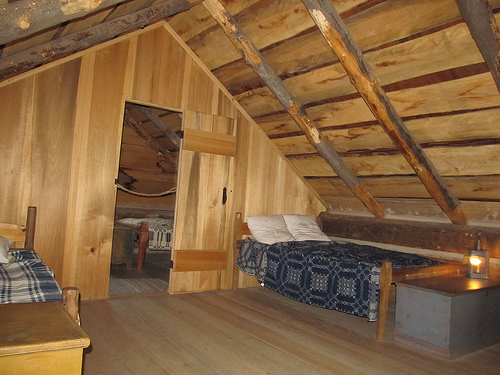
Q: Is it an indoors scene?
A: Yes, it is indoors.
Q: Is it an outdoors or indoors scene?
A: It is indoors.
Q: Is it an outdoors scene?
A: No, it is indoors.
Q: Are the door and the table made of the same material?
A: Yes, both the door and the table are made of wood.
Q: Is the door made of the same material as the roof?
A: Yes, both the door and the roof are made of wood.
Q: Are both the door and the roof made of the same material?
A: Yes, both the door and the roof are made of wood.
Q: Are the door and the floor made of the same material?
A: Yes, both the door and the floor are made of wood.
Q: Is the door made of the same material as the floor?
A: Yes, both the door and the floor are made of wood.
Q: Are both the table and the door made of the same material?
A: Yes, both the table and the door are made of wood.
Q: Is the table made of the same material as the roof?
A: Yes, both the table and the roof are made of wood.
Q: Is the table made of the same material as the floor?
A: Yes, both the table and the floor are made of wood.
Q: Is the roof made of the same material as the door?
A: Yes, both the roof and the door are made of wood.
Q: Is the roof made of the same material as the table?
A: Yes, both the roof and the table are made of wood.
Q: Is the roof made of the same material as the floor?
A: Yes, both the roof and the floor are made of wood.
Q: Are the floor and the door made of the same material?
A: Yes, both the floor and the door are made of wood.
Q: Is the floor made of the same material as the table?
A: Yes, both the floor and the table are made of wood.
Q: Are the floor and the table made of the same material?
A: Yes, both the floor and the table are made of wood.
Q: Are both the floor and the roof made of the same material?
A: Yes, both the floor and the roof are made of wood.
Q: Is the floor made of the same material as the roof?
A: Yes, both the floor and the roof are made of wood.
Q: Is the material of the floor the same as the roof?
A: Yes, both the floor and the roof are made of wood.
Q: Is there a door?
A: Yes, there is a door.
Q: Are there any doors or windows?
A: Yes, there is a door.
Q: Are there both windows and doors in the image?
A: No, there is a door but no windows.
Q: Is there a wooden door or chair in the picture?
A: Yes, there is a wood door.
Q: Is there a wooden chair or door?
A: Yes, there is a wood door.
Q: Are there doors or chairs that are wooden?
A: Yes, the door is wooden.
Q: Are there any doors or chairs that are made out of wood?
A: Yes, the door is made of wood.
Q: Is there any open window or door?
A: Yes, there is an open door.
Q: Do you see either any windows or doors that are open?
A: Yes, the door is open.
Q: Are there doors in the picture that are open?
A: Yes, there is an open door.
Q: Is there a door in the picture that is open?
A: Yes, there is a door that is open.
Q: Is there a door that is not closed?
A: Yes, there is a open door.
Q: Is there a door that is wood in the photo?
A: Yes, there is a wood door.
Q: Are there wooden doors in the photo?
A: Yes, there is a wood door.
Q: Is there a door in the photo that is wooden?
A: Yes, there is a door that is wooden.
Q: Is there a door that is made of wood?
A: Yes, there is a door that is made of wood.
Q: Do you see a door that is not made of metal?
A: Yes, there is a door that is made of wood.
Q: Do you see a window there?
A: No, there are no windows.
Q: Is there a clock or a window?
A: No, there are no windows or clocks.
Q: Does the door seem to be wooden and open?
A: Yes, the door is wooden and open.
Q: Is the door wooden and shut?
A: No, the door is wooden but open.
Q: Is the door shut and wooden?
A: No, the door is wooden but open.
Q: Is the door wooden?
A: Yes, the door is wooden.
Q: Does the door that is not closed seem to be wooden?
A: Yes, the door is wooden.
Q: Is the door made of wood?
A: Yes, the door is made of wood.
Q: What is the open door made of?
A: The door is made of wood.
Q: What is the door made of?
A: The door is made of wood.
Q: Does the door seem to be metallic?
A: No, the door is wooden.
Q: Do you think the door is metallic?
A: No, the door is wooden.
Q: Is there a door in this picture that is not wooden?
A: No, there is a door but it is wooden.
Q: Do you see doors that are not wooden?
A: No, there is a door but it is wooden.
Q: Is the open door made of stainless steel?
A: No, the door is made of wood.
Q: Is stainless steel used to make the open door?
A: No, the door is made of wood.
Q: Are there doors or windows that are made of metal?
A: No, there is a door but it is made of wood.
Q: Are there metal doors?
A: No, there is a door but it is made of wood.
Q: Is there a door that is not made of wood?
A: No, there is a door but it is made of wood.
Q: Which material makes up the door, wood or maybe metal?
A: The door is made of wood.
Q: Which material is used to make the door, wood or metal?
A: The door is made of wood.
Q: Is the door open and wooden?
A: Yes, the door is open and wooden.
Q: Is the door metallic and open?
A: No, the door is open but wooden.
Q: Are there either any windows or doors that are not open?
A: No, there is a door but it is open.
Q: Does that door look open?
A: Yes, the door is open.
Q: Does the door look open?
A: Yes, the door is open.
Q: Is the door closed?
A: No, the door is open.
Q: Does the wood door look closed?
A: No, the door is open.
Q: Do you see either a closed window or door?
A: No, there is a door but it is open.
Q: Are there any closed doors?
A: No, there is a door but it is open.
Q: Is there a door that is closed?
A: No, there is a door but it is open.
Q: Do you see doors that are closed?
A: No, there is a door but it is open.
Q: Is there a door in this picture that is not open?
A: No, there is a door but it is open.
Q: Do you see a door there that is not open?
A: No, there is a door but it is open.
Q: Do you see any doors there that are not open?
A: No, there is a door but it is open.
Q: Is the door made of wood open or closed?
A: The door is open.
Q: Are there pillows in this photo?
A: Yes, there is a pillow.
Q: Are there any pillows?
A: Yes, there is a pillow.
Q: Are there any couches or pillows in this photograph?
A: Yes, there is a pillow.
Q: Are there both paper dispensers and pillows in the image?
A: No, there is a pillow but no paper dispensers.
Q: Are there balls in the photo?
A: No, there are no balls.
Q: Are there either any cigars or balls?
A: No, there are no balls or cigars.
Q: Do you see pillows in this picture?
A: Yes, there is a pillow.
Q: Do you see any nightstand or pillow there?
A: Yes, there is a pillow.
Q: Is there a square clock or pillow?
A: Yes, there is a square pillow.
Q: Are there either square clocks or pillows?
A: Yes, there is a square pillow.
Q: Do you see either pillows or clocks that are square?
A: Yes, the pillow is square.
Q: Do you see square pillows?
A: Yes, there is a square pillow.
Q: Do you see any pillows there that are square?
A: Yes, there is a pillow that is square.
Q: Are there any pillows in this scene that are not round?
A: Yes, there is a square pillow.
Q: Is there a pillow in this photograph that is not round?
A: Yes, there is a square pillow.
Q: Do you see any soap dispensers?
A: No, there are no soap dispensers.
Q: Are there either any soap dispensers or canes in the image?
A: No, there are no soap dispensers or canes.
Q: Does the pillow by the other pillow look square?
A: Yes, the pillow is square.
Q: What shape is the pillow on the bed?
A: The pillow is square.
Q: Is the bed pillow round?
A: No, the pillow is square.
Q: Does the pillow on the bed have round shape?
A: No, the pillow is square.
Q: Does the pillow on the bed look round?
A: No, the pillow is square.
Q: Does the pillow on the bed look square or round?
A: The pillow is square.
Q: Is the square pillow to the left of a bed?
A: No, the pillow is to the right of a bed.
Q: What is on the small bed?
A: The pillow is on the bed.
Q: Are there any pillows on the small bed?
A: Yes, there is a pillow on the bed.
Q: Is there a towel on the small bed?
A: No, there is a pillow on the bed.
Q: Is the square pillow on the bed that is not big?
A: Yes, the pillow is on the bed.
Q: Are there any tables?
A: Yes, there is a table.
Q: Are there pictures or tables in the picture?
A: Yes, there is a table.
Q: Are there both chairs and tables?
A: No, there is a table but no chairs.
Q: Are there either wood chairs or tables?
A: Yes, there is a wood table.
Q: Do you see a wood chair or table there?
A: Yes, there is a wood table.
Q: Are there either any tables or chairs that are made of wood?
A: Yes, the table is made of wood.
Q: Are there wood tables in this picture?
A: Yes, there is a wood table.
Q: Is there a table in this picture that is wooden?
A: Yes, there is a table that is wooden.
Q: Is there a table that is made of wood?
A: Yes, there is a table that is made of wood.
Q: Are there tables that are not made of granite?
A: Yes, there is a table that is made of wood.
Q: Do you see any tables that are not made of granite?
A: Yes, there is a table that is made of wood.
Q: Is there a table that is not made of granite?
A: Yes, there is a table that is made of wood.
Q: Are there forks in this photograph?
A: No, there are no forks.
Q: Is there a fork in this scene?
A: No, there are no forks.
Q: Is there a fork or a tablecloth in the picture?
A: No, there are no forks or tablecloths.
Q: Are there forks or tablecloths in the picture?
A: No, there are no forks or tablecloths.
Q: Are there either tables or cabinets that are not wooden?
A: No, there is a table but it is wooden.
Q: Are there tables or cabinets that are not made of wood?
A: No, there is a table but it is made of wood.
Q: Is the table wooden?
A: Yes, the table is wooden.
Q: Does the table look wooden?
A: Yes, the table is wooden.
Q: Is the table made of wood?
A: Yes, the table is made of wood.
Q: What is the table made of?
A: The table is made of wood.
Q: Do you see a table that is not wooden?
A: No, there is a table but it is wooden.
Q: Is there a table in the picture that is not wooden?
A: No, there is a table but it is wooden.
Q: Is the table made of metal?
A: No, the table is made of wood.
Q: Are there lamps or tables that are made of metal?
A: No, there is a table but it is made of wood.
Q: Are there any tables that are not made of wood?
A: No, there is a table but it is made of wood.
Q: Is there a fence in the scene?
A: No, there are no fences.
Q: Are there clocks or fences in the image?
A: No, there are no fences or clocks.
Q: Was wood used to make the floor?
A: Yes, the floor is made of wood.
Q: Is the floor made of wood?
A: Yes, the floor is made of wood.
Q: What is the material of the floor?
A: The floor is made of wood.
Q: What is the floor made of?
A: The floor is made of wood.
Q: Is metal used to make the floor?
A: No, the floor is made of wood.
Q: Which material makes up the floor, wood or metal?
A: The floor is made of wood.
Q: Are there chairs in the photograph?
A: No, there are no chairs.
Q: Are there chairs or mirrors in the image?
A: No, there are no chairs or mirrors.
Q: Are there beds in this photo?
A: Yes, there is a bed.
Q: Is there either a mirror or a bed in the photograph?
A: Yes, there is a bed.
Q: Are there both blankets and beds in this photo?
A: Yes, there are both a bed and a blanket.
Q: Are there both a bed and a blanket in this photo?
A: Yes, there are both a bed and a blanket.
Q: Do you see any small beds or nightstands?
A: Yes, there is a small bed.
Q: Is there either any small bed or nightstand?
A: Yes, there is a small bed.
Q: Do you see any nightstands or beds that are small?
A: Yes, the bed is small.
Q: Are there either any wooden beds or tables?
A: Yes, there is a wood bed.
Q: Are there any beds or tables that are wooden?
A: Yes, the bed is wooden.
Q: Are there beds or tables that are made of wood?
A: Yes, the bed is made of wood.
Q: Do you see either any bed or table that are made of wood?
A: Yes, the bed is made of wood.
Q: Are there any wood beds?
A: Yes, there is a wood bed.